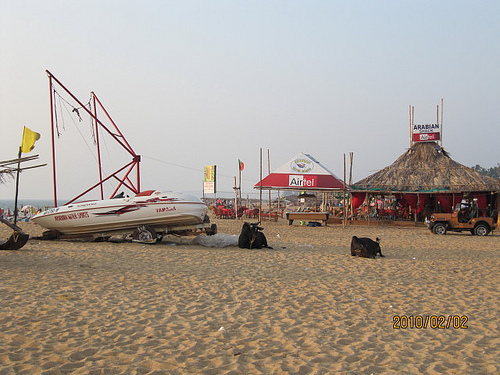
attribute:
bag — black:
[351, 235, 382, 260]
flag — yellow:
[18, 124, 40, 155]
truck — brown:
[423, 196, 494, 238]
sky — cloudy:
[1, 4, 499, 182]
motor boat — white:
[26, 185, 221, 252]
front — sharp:
[26, 206, 58, 235]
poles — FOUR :
[403, 95, 445, 125]